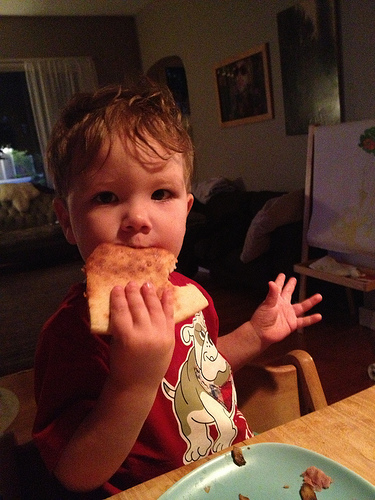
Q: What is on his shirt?
A: A cartoon bulldog.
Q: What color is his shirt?
A: Red.